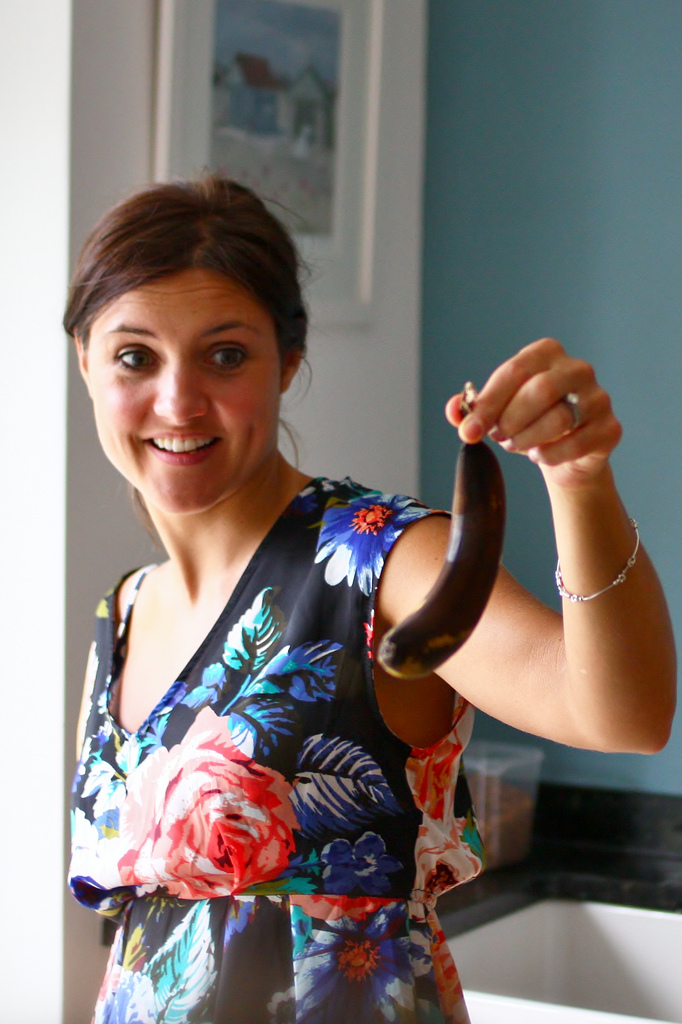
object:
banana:
[377, 384, 506, 682]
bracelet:
[555, 518, 640, 606]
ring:
[563, 388, 582, 431]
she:
[0, 167, 679, 1022]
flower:
[113, 736, 302, 908]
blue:
[278, 641, 338, 702]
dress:
[66, 473, 488, 1021]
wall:
[0, 750, 66, 1023]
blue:
[336, 985, 362, 1015]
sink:
[435, 896, 681, 1020]